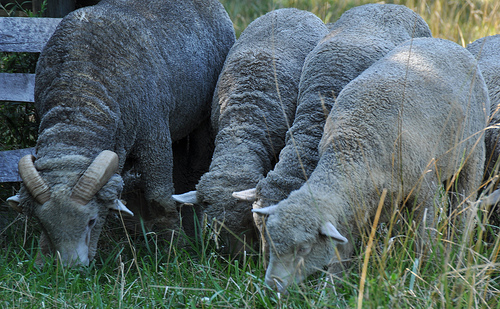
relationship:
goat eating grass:
[9, 1, 289, 286] [2, 246, 478, 306]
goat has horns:
[6, 1, 237, 274] [21, 157, 49, 202]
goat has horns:
[6, 1, 237, 274] [71, 149, 116, 194]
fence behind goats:
[0, 17, 64, 182] [9, 3, 484, 285]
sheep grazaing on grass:
[0, 0, 499, 294] [2, 0, 499, 307]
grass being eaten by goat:
[2, 0, 499, 307] [6, 1, 237, 274]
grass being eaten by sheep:
[2, 0, 499, 307] [176, 7, 330, 263]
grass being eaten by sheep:
[2, 0, 499, 307] [231, 2, 431, 272]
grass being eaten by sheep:
[2, 0, 499, 307] [259, 37, 489, 287]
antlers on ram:
[16, 150, 118, 202] [3, 2, 237, 270]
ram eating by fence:
[6, 11, 235, 304] [1, 4, 54, 217]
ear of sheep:
[317, 220, 346, 244] [259, 37, 489, 287]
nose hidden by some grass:
[262, 266, 300, 305] [225, 271, 302, 307]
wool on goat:
[242, 33, 283, 127] [6, 1, 237, 274]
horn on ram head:
[18, 152, 51, 202] [5, 0, 236, 272]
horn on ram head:
[71, 147, 119, 202] [5, 0, 236, 272]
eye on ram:
[77, 212, 102, 231] [8, 144, 141, 204]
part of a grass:
[157, 278, 181, 297] [0, 160, 498, 307]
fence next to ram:
[0, 13, 64, 185] [3, 2, 237, 270]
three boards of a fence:
[0, 11, 51, 192] [1, 16, 45, 215]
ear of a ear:
[319, 221, 348, 245] [250, 200, 280, 222]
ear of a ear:
[319, 221, 348, 245] [227, 181, 259, 205]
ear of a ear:
[319, 221, 348, 245] [108, 193, 136, 221]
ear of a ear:
[319, 221, 348, 245] [2, 187, 23, 212]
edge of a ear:
[322, 226, 342, 244] [319, 221, 348, 245]